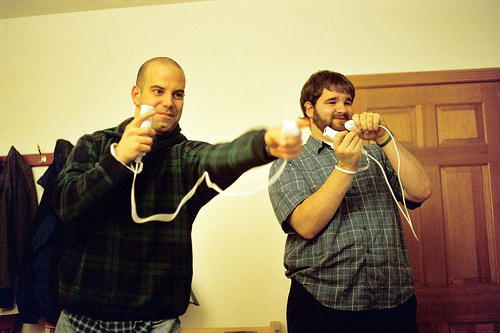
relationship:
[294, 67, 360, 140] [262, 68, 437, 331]
head of person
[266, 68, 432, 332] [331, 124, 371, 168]
guy has hand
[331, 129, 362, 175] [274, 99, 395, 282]
hand hand of man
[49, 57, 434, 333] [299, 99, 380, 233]
two men playing nintendo wii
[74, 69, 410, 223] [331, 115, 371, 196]
two men playing nintendo wii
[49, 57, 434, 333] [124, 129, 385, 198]
two men playing nintendo wii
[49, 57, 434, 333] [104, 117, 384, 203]
two men playing nintendo wii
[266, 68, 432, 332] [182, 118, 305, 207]
guy has arm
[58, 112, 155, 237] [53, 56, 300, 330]
arm of person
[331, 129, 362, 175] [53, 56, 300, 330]
hand of person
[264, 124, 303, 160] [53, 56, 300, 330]
hand of person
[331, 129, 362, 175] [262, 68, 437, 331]
hand of person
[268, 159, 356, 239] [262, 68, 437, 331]
arm of person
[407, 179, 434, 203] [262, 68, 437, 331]
elbow of person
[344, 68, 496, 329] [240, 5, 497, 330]
door on right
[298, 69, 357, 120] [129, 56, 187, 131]
hair on head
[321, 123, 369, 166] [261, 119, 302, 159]
controller in hand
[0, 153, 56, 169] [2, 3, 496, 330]
coat rack on wall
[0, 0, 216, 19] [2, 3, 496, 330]
ceiling of wall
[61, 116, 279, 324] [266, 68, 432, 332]
shirt on guy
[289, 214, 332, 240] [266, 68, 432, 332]
elbow of guy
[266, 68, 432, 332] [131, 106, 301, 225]
guy playing wii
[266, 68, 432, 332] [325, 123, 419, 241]
guy playing wii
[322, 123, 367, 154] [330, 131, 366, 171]
controller in hand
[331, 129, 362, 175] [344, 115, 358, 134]
hand holding nunchuck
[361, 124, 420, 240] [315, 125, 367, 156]
cord connected to controller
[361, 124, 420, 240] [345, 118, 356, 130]
cord connected to nunchuck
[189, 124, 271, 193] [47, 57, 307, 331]
arm in front of body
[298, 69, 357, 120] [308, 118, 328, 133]
hair along jawline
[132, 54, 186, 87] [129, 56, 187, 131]
stubble on head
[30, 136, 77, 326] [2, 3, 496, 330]
jacket hanging on wall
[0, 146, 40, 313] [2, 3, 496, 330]
jacket hanging on wall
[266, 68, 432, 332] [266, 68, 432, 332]
guy standing by guy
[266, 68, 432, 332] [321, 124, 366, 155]
guy holding remote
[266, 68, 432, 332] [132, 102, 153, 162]
guy holding remote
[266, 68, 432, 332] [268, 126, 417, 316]
guy wearing shirt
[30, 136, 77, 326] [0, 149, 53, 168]
jacket hanging on rack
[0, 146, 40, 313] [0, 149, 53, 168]
jacket hanging on rack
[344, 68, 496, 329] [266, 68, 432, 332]
door behind guy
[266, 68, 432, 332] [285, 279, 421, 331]
guy wearing bottoms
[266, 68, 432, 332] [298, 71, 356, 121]
guy has hair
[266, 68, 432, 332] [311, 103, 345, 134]
guy has beard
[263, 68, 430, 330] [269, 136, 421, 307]
guy wearing shirt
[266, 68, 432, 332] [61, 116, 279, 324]
guy wearing shirt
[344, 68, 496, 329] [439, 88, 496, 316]
door made of wood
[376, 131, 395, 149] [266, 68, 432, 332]
band around guy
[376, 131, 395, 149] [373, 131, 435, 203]
band around arm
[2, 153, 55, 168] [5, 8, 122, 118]
coat rack on wall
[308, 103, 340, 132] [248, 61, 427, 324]
hair on man